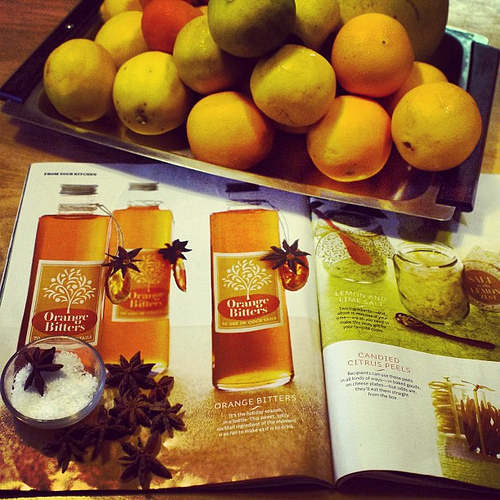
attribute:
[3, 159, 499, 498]
magazine — open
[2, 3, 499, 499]
table — wooden, brown, wood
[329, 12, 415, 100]
orange — round, citrus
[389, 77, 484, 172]
orange — round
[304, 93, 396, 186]
orange — citrus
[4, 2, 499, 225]
plate — metal, silver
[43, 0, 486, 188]
fruit — piled, citrus, piled high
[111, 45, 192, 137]
lemon — yellow, green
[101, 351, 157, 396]
star anise — brown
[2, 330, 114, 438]
bowl — glass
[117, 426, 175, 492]
star anise — brown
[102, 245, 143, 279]
star anise — brown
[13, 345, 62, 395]
star anise — brown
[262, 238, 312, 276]
star anise — brown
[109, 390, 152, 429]
star anise — brown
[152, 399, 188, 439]
star anise — brown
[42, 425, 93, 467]
star anise — brown